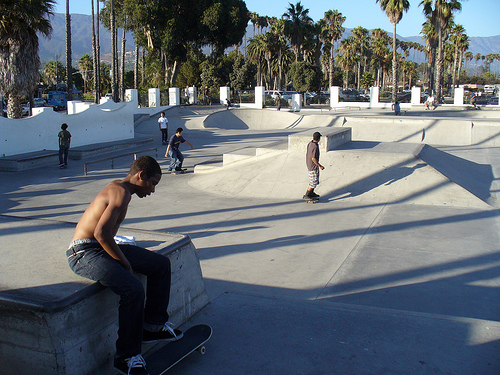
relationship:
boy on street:
[64, 154, 184, 375] [1, 201, 499, 374]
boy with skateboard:
[64, 154, 184, 375] [121, 322, 220, 375]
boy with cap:
[64, 154, 184, 375] [312, 129, 322, 140]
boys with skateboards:
[55, 95, 325, 374] [80, 127, 331, 374]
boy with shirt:
[157, 111, 169, 145] [156, 114, 171, 132]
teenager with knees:
[164, 127, 194, 176] [169, 152, 186, 162]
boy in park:
[64, 154, 184, 375] [2, 74, 497, 375]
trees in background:
[0, 0, 499, 118] [0, 0, 498, 127]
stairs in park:
[193, 123, 356, 180] [2, 74, 497, 375]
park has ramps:
[2, 74, 497, 375] [191, 101, 490, 216]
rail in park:
[80, 147, 160, 178] [2, 74, 497, 375]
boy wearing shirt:
[294, 127, 325, 207] [298, 141, 321, 173]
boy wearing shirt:
[155, 111, 172, 144] [156, 114, 171, 132]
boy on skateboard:
[155, 111, 172, 144] [161, 141, 173, 151]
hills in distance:
[2, 6, 500, 92] [3, 2, 499, 86]